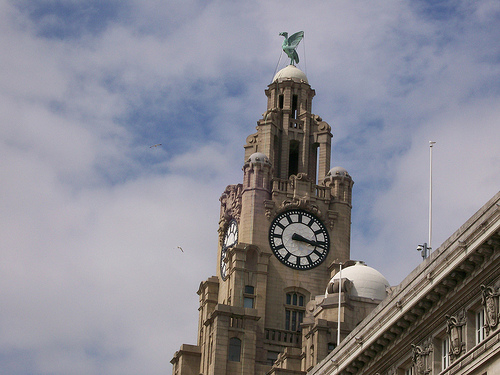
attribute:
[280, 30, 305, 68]
statue — stone, green, antique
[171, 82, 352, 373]
clock tower — large, brick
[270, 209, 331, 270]
clock — white, black, circular, reading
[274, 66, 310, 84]
dome — white, cream, taupe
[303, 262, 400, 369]
building — stone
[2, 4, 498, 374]
sky — cloudy, blue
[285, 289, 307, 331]
window — arched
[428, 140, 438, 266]
lightning rod — white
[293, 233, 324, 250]
hand — black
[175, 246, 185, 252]
bird — small